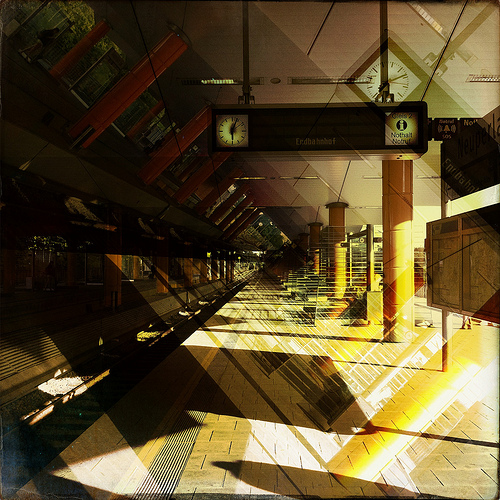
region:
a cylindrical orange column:
[377, 159, 420, 341]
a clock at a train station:
[212, 109, 255, 154]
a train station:
[2, 9, 496, 498]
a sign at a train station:
[421, 201, 498, 325]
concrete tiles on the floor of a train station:
[269, 324, 476, 490]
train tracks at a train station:
[15, 306, 189, 420]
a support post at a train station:
[363, 217, 377, 298]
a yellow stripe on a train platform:
[118, 340, 217, 498]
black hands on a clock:
[226, 113, 241, 144]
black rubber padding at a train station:
[131, 344, 234, 497]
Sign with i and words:
[366, 101, 438, 146]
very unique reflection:
[223, 298, 461, 488]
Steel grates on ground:
[146, 313, 257, 483]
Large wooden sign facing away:
[406, 225, 493, 337]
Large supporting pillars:
[291, 201, 428, 317]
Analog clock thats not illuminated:
[198, 110, 268, 150]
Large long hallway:
[136, 192, 331, 419]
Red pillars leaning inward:
[68, 67, 228, 158]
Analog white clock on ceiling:
[348, 47, 437, 104]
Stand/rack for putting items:
[282, 278, 368, 324]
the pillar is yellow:
[308, 74, 494, 261]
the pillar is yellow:
[313, 93, 463, 385]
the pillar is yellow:
[391, 89, 468, 379]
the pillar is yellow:
[364, 18, 447, 394]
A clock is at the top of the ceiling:
[345, 44, 427, 96]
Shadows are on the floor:
[143, 306, 425, 496]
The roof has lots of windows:
[20, 15, 308, 252]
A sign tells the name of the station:
[212, 92, 434, 164]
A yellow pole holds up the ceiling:
[373, 155, 446, 367]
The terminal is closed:
[277, 221, 377, 333]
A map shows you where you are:
[421, 203, 497, 342]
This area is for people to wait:
[19, 258, 135, 317]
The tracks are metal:
[12, 357, 121, 429]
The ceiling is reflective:
[349, 14, 469, 117]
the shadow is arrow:
[246, 330, 387, 481]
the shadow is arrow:
[250, 252, 358, 416]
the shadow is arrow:
[196, 237, 304, 488]